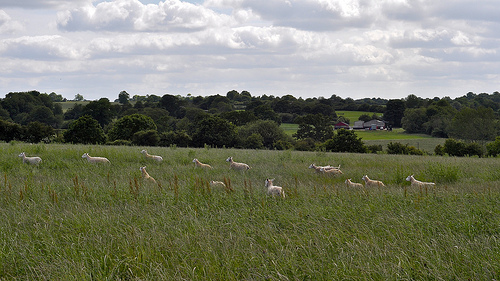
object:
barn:
[355, 112, 401, 135]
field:
[0, 139, 484, 279]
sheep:
[261, 174, 286, 197]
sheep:
[343, 176, 363, 190]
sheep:
[360, 171, 385, 188]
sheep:
[136, 163, 158, 184]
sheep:
[80, 150, 111, 166]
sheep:
[15, 142, 444, 201]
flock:
[8, 138, 454, 228]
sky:
[51, 9, 302, 74]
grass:
[97, 202, 271, 272]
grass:
[90, 202, 300, 278]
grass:
[18, 148, 438, 195]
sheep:
[19, 155, 435, 205]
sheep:
[13, 149, 439, 196]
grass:
[205, 210, 311, 252]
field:
[33, 163, 427, 273]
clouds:
[59, 6, 221, 36]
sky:
[23, 11, 442, 132]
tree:
[67, 99, 120, 144]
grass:
[45, 131, 165, 176]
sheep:
[339, 174, 368, 194]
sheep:
[313, 156, 337, 175]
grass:
[295, 182, 375, 220]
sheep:
[10, 147, 48, 174]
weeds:
[119, 174, 146, 204]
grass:
[53, 186, 273, 276]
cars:
[368, 122, 393, 131]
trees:
[393, 84, 495, 160]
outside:
[0, 5, 494, 271]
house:
[336, 109, 394, 134]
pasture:
[3, 137, 496, 275]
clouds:
[3, 6, 497, 68]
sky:
[0, 0, 498, 108]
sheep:
[261, 175, 289, 204]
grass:
[9, 141, 497, 278]